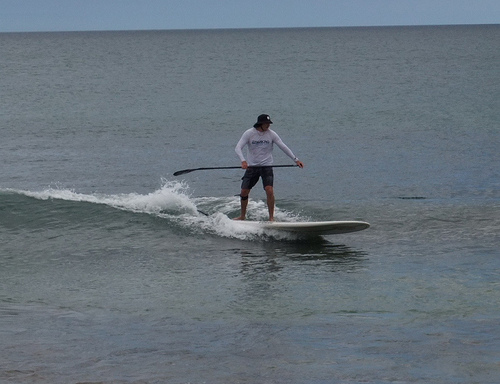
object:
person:
[233, 113, 308, 224]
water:
[0, 30, 499, 383]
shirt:
[232, 126, 296, 168]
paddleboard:
[213, 220, 372, 236]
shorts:
[235, 165, 282, 193]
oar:
[172, 164, 304, 177]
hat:
[252, 114, 272, 129]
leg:
[234, 165, 253, 218]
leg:
[261, 168, 275, 221]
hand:
[239, 158, 249, 170]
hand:
[297, 160, 304, 169]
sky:
[0, 0, 499, 37]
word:
[251, 140, 257, 146]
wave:
[0, 179, 281, 244]